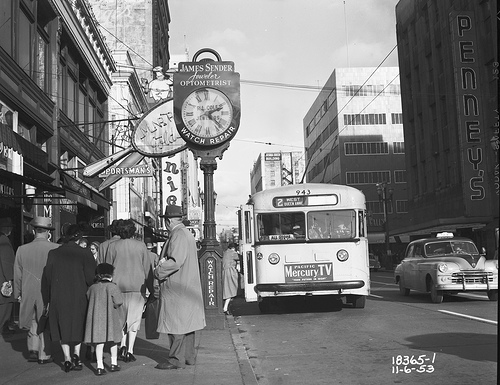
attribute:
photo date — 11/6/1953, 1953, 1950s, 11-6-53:
[392, 366, 435, 374]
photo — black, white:
[0, 1, 493, 381]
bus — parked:
[237, 183, 371, 313]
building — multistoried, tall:
[384, 1, 500, 262]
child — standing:
[85, 263, 122, 375]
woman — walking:
[41, 223, 98, 373]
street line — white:
[439, 309, 499, 326]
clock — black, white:
[173, 48, 241, 329]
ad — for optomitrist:
[177, 64, 234, 88]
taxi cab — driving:
[394, 232, 499, 303]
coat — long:
[43, 241, 97, 342]